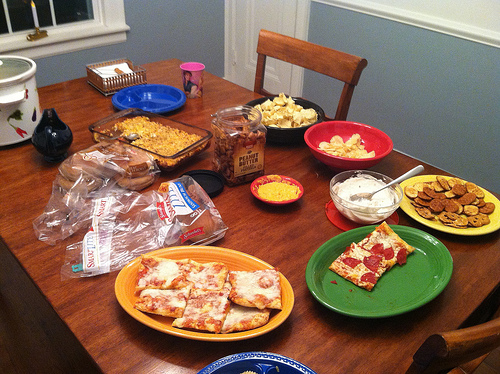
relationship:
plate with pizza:
[311, 222, 447, 319] [335, 226, 410, 286]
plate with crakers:
[399, 170, 499, 240] [412, 184, 486, 225]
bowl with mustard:
[247, 171, 304, 205] [261, 177, 296, 201]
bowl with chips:
[311, 116, 390, 174] [325, 139, 371, 158]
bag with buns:
[81, 186, 230, 257] [165, 185, 221, 236]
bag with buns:
[37, 143, 157, 241] [62, 147, 148, 195]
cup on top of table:
[179, 62, 209, 101] [11, 61, 490, 374]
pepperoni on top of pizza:
[365, 246, 408, 283] [335, 226, 410, 286]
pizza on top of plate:
[335, 226, 410, 286] [311, 222, 447, 319]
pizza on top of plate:
[146, 260, 277, 325] [110, 245, 296, 338]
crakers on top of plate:
[412, 184, 486, 225] [399, 170, 499, 240]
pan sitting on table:
[86, 108, 213, 167] [11, 61, 490, 374]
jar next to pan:
[210, 110, 269, 186] [86, 108, 213, 167]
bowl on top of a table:
[245, 93, 325, 142] [11, 61, 490, 374]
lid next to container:
[179, 169, 229, 200] [210, 110, 269, 186]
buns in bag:
[165, 185, 221, 236] [81, 186, 230, 257]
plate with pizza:
[110, 245, 296, 338] [146, 260, 277, 325]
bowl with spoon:
[332, 169, 402, 221] [351, 163, 425, 201]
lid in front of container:
[179, 169, 229, 200] [210, 110, 269, 186]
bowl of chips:
[311, 116, 390, 174] [325, 139, 371, 158]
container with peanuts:
[210, 110, 269, 186] [211, 126, 260, 182]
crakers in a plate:
[412, 184, 486, 225] [399, 170, 499, 240]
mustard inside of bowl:
[261, 177, 296, 201] [247, 171, 304, 205]